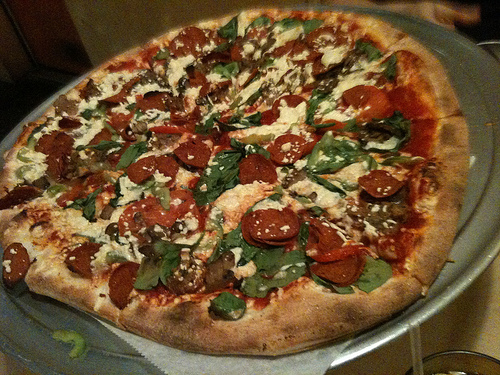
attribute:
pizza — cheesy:
[184, 44, 238, 76]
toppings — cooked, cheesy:
[315, 175, 369, 221]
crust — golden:
[120, 47, 146, 68]